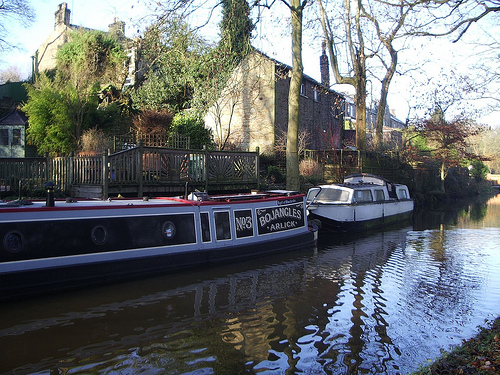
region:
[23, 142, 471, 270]
boats in a river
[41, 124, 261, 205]
railing made of wood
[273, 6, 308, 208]
trees near the river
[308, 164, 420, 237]
the boat is white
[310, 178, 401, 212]
the boat has windows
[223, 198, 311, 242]
there are words on the side of the boat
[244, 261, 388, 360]
reflection of trees on the river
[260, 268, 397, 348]
the water is calm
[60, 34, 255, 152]
the trees have green leaves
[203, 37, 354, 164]
house made of brick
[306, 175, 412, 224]
a small white boat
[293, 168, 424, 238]
a small boat floating on water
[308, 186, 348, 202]
a dirty front windshield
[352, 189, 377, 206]
a window on a boat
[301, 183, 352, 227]
the front of a small boat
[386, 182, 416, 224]
the back of a boat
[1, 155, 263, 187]
a wooden deck fence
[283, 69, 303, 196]
a tall tree trunk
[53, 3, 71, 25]
a house chimney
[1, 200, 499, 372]
rippling water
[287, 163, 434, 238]
white boat on water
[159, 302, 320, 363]
the water is murky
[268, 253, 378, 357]
the water is murky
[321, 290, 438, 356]
the water is murky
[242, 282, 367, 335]
the water is murky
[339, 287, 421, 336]
light reflecting on the surface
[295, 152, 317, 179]
a dry brown shrub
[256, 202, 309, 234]
a company name on a boat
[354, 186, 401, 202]
window in boat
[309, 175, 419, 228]
small white fisherman boat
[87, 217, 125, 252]
circular window in dock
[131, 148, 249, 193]
wooden railing on dock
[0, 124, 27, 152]
dark windows in white house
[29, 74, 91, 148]
a fluffy green tree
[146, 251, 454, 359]
dark brown river water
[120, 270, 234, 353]
the water is murky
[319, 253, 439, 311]
the water is murky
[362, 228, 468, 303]
the water is murky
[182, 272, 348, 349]
the water is murky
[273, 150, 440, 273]
the boat is white